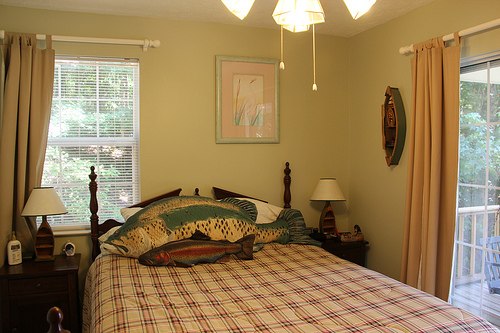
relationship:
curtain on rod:
[0, 32, 55, 261] [0, 30, 160, 51]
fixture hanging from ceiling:
[237, 19, 411, 119] [1, 0, 433, 38]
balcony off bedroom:
[421, 160, 489, 321] [0, 1, 499, 331]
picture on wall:
[213, 52, 281, 143] [0, 11, 362, 257]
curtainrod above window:
[396, 17, 499, 57] [403, 47, 499, 324]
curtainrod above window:
[0, 27, 160, 49] [6, 48, 139, 225]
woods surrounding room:
[457, 84, 499, 271] [3, 0, 499, 331]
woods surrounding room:
[38, 57, 134, 227] [3, 0, 499, 331]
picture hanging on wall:
[207, 46, 290, 150] [4, 3, 361, 276]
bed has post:
[72, 155, 491, 332] [281, 157, 301, 220]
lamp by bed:
[309, 179, 348, 240] [72, 155, 491, 332]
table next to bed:
[7, 260, 88, 324] [82, 168, 499, 331]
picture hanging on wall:
[213, 52, 281, 143] [0, 1, 500, 307]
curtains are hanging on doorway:
[402, 31, 459, 304] [440, 54, 497, 332]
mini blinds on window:
[41, 59, 133, 223] [32, 58, 141, 228]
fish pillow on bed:
[139, 229, 256, 268] [72, 155, 491, 332]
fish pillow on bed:
[99, 194, 323, 256] [72, 155, 491, 332]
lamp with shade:
[309, 179, 348, 240] [303, 175, 345, 202]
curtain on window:
[4, 30, 47, 168] [43, 63, 149, 168]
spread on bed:
[247, 265, 363, 327] [93, 262, 454, 322]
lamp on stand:
[309, 179, 348, 240] [301, 225, 383, 270]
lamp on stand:
[14, 177, 64, 257] [2, 247, 99, 331]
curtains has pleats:
[402, 36, 461, 303] [417, 87, 447, 162]